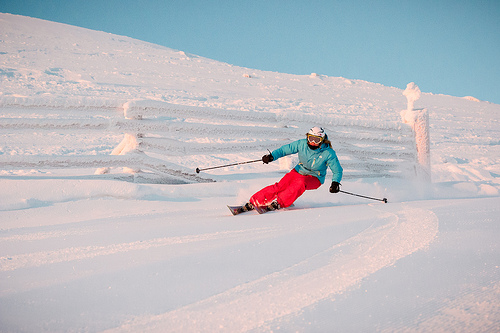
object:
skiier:
[226, 126, 342, 218]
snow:
[0, 204, 204, 332]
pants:
[249, 168, 322, 208]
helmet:
[306, 126, 325, 140]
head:
[306, 126, 325, 150]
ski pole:
[339, 190, 387, 203]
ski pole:
[195, 159, 262, 174]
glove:
[329, 181, 340, 193]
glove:
[262, 149, 274, 165]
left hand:
[328, 183, 339, 194]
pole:
[399, 82, 432, 183]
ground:
[0, 10, 499, 331]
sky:
[347, 1, 497, 72]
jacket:
[270, 139, 344, 183]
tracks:
[3, 215, 416, 282]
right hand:
[262, 155, 274, 165]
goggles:
[308, 134, 324, 145]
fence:
[1, 94, 147, 170]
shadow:
[290, 201, 363, 210]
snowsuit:
[249, 133, 344, 208]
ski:
[254, 200, 280, 215]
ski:
[226, 202, 255, 216]